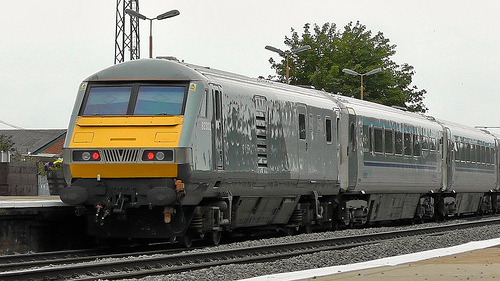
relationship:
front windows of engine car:
[80, 86, 183, 116] [58, 56, 500, 248]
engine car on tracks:
[58, 56, 500, 248] [0, 216, 498, 278]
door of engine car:
[295, 103, 306, 180] [58, 56, 500, 248]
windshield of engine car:
[82, 85, 182, 116] [58, 56, 500, 248]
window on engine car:
[365, 125, 496, 164] [58, 56, 500, 248]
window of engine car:
[399, 132, 410, 155] [58, 56, 500, 248]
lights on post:
[342, 67, 382, 76] [280, 52, 289, 81]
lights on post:
[340, 64, 386, 77] [356, 76, 364, 99]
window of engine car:
[365, 125, 496, 164] [58, 56, 500, 248]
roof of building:
[0, 128, 70, 155] [3, 123, 66, 155]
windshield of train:
[82, 87, 183, 116] [56, 47, 415, 254]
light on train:
[130, 130, 196, 170] [23, 49, 385, 238]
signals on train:
[88, 133, 173, 168] [64, 33, 427, 240]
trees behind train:
[252, 11, 451, 155] [64, 33, 427, 240]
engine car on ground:
[58, 56, 500, 248] [31, 215, 499, 262]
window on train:
[365, 125, 496, 164] [53, 47, 472, 246]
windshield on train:
[82, 87, 183, 116] [47, 41, 449, 239]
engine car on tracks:
[58, 56, 500, 248] [6, 230, 482, 279]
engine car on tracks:
[58, 56, 500, 248] [102, 242, 294, 278]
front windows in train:
[80, 86, 183, 116] [53, 47, 472, 246]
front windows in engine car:
[80, 86, 183, 116] [58, 56, 500, 248]